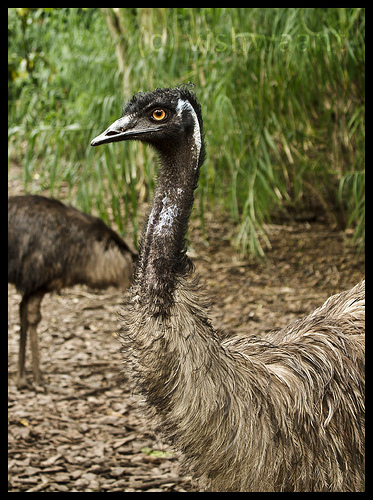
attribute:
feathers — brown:
[139, 286, 362, 494]